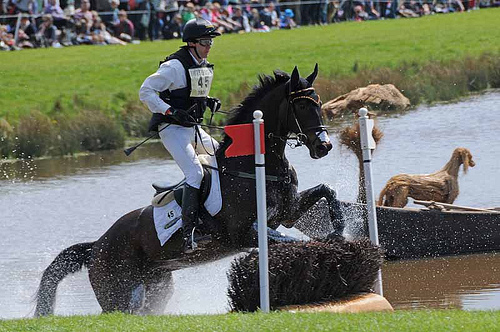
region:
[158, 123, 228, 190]
man wearing white pants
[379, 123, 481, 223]
dog standing in the water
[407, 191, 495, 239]
paddle in the boat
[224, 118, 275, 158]
red flag on the pole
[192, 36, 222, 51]
man wearing safety goggles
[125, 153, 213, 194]
black saddle on the horse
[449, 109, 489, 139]
water in the river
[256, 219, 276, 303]
the pole is white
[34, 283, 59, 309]
tail on the horse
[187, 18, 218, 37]
a helmet the man is wearing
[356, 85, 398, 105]
a rock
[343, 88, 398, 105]
the rock is brown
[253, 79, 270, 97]
the horse has black hair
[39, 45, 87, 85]
the grass is green and short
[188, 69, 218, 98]
a sign the jockey is wearing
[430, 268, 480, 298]
the water is brown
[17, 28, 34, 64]
a person in a distance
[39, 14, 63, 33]
a person in a distance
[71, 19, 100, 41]
a person in a distance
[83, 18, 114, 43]
a person in a distance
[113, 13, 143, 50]
a person in a distance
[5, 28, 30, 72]
a person in a distance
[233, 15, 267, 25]
a person in a distance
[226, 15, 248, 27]
a person in a distance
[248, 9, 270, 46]
a person in a distance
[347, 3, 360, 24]
a person in a distance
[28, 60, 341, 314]
a black horse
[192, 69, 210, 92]
45 on the chest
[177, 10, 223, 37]
a hat on head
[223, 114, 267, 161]
a red flag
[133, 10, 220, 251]
a male rider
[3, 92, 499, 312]
a pond in the area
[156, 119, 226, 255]
white pants on the man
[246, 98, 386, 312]
two flag poles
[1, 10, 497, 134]
the grassy field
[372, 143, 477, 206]
the tan dog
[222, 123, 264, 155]
A red flag on a white pole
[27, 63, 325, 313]
A horse jumping from the water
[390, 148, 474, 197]
A wet dog standing in a boat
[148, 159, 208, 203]
A saddle on a horse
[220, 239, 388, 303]
A plant near the shore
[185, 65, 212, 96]
A white bib with a number on it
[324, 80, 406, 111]
A large rock beside water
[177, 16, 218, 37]
A black helmet on a man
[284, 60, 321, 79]
Pointed ears on a horse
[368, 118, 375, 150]
A white flag on a pole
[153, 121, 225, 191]
man wearing white pants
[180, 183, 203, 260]
man wearing black riding boot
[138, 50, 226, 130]
man wearing black vest with white number sign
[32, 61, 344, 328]
black horse jumping competitively